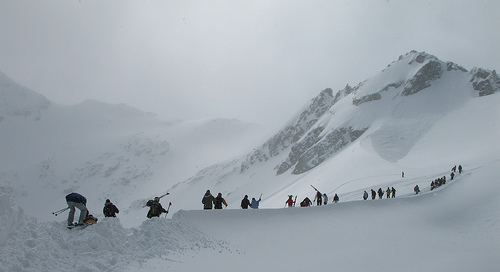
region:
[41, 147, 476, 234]
skiers moving in single file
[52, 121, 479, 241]
skiers ascending a mountain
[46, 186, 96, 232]
skier deeply bent over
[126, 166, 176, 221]
skier holding poles at different angles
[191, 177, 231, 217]
skiers traveling as a pair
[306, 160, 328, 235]
person holding skis over shoulder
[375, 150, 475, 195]
lone skier ahead of the group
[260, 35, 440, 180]
peaks at the top of the mountain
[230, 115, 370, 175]
exposed tips of mountainous outcrops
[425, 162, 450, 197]
skiers spaced evenly across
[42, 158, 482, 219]
A line of people on a mountain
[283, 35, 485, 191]
Mountain is covered in snow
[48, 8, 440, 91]
Sky is gray and cloudy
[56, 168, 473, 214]
People are traveling up the snow hill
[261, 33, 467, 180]
Mountain is black and white in color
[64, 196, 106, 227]
Person is wearing light colored pants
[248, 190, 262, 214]
Person is wearing a blue coat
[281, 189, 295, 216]
Person is wearing a red coat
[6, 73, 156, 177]
Mountains are on the left side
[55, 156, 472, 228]
Line of people are moving to the right of image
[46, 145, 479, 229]
People hiking in the snow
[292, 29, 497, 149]
Snowed covered mountain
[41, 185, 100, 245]
Man bending over with a bag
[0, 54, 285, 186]
Snow capped mountains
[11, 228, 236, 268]
Snow that has been walked in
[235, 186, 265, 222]
Two people walking together in the snow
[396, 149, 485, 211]
People trailing behind one person walking ahead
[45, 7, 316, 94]
Gray sky over snow covered mountains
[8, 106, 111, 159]
Fresh snow on side of mountain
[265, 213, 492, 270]
Untouched snow on mountain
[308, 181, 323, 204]
skiers hiking up a mountain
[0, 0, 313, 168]
a whiteout from the fog and blowing snow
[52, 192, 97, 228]
a hiker repacking his backpack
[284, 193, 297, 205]
a hiker wearing a red jacket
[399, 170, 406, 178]
a lead hiker way in the front of the group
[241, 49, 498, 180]
a small mountain ahead of the group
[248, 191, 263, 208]
a hiker wearing a blue ski jacket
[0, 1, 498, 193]
fog and blowing snow cause poor visibility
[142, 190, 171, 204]
the hiker is carrying his ski's on his shoulder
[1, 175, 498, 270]
piles of snow formed a snowbank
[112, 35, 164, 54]
the sky is covered by clouds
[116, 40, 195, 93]
the clouds are grey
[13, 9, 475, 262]
it is snowing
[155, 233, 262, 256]
snow covers the ground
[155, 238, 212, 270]
the snow is white in color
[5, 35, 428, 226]
it is in a mountain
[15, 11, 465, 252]
it is a daytime scene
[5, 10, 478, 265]
it is an outdoor scene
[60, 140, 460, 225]
the people are walking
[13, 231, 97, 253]
trails are in the snow